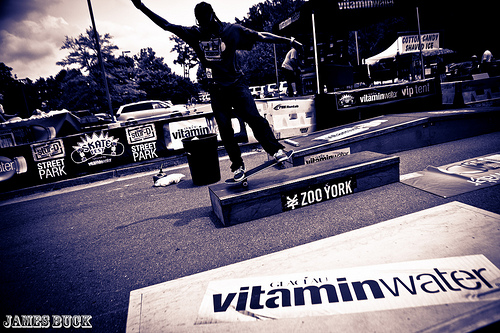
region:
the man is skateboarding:
[177, 4, 349, 248]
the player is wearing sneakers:
[201, 129, 337, 209]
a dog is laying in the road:
[144, 160, 196, 197]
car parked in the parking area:
[101, 94, 201, 131]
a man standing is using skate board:
[122, 0, 315, 197]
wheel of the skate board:
[238, 176, 250, 190]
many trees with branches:
[41, 38, 182, 110]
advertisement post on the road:
[20, 115, 201, 172]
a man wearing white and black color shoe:
[272, 143, 294, 171]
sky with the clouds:
[4, 19, 52, 64]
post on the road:
[88, 10, 123, 136]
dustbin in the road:
[176, 125, 235, 193]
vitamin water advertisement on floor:
[201, 255, 498, 315]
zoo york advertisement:
[280, 177, 366, 211]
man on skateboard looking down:
[175, 5, 350, 181]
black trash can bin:
[161, 121, 236, 189]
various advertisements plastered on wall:
[8, 116, 173, 170]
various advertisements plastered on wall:
[333, 81, 440, 110]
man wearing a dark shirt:
[170, 1, 307, 186]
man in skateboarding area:
[168, 93, 473, 215]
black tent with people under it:
[265, 0, 444, 90]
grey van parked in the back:
[114, 93, 186, 122]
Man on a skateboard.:
[131, 1, 433, 226]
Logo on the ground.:
[153, 237, 400, 328]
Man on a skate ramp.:
[173, 8, 380, 241]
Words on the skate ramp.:
[255, 173, 430, 218]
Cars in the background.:
[39, 39, 199, 161]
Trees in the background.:
[38, 22, 238, 159]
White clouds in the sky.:
[5, 4, 96, 81]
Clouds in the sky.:
[16, 9, 132, 87]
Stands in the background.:
[310, 18, 473, 112]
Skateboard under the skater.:
[200, 153, 396, 213]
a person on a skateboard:
[132, 0, 339, 217]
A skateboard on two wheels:
[215, 138, 311, 220]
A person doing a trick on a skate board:
[142, 1, 321, 201]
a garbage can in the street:
[180, 127, 222, 187]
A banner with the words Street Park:
[30, 156, 70, 186]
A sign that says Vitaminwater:
[203, 261, 496, 323]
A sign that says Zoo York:
[292, 176, 357, 206]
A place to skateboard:
[182, 96, 490, 238]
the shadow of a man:
[111, 197, 215, 242]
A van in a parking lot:
[110, 86, 205, 128]